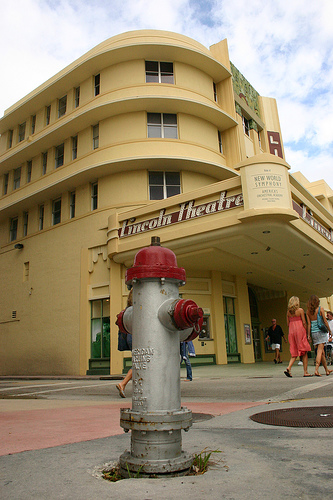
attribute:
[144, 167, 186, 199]
window — closed, glass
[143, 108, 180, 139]
window — closed, glass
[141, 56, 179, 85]
window — closed, glass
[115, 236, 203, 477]
fire hydrant — red, silver, painted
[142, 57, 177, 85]
window — top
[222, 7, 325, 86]
clouds — fluffy, white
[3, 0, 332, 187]
sky — white, blue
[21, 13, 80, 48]
clouds — white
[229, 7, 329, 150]
sky — blue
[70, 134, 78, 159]
window — high, glass, closed, square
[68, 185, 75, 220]
window — square, closed, glass, high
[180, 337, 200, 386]
person — dressed, walking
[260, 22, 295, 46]
clouds — fluffy, white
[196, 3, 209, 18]
sky — white, blue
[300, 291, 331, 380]
person — girl, walking, dressed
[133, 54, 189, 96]
window — high, glass, closed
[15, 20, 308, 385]
building — theatre, large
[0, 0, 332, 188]
clouds — fluffy, white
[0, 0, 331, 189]
blue sky — white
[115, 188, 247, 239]
words — off, bulbs, lincoln theatre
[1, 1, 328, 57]
clouds — white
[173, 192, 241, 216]
word — off, light bulbs, theatre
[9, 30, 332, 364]
building — theatre, large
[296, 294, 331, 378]
person — walking, dressed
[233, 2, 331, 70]
clouds — white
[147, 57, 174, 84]
window — high, closed, glass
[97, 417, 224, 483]
base — silver, metal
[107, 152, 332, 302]
front awning — painted, tan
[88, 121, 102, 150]
window — high, closed, glass, square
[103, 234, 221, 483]
hydrant — closed, metal, red, silver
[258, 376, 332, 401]
crosswalk line — white, painted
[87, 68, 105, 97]
window — square, closed, glass, high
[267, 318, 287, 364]
person — walking, man, dressed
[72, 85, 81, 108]
window — square, glass, closed, high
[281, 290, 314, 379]
person — dressed, girl, walking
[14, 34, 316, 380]
theater — closed, large, tan, painted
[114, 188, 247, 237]
word — off, lights, lincoln theatre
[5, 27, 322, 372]
theatre — closed, tan, large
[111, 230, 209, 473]
hydrant — off, silver, red, metal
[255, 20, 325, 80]
sky — blue